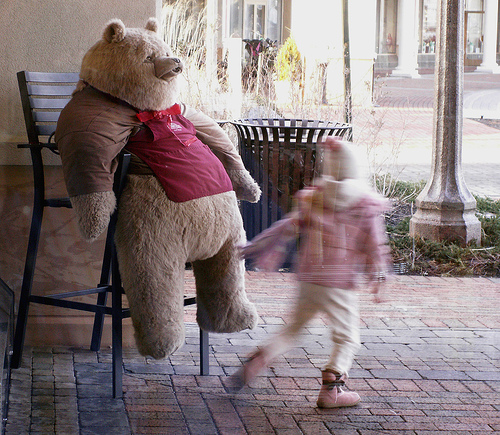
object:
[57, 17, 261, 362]
teddy bear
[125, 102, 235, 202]
apron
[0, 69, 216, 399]
chair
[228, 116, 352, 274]
garbage can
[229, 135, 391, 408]
girl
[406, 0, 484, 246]
lamp post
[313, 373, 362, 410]
boot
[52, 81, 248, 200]
t shirt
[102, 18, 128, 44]
ear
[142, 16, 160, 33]
ear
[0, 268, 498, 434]
sidewalk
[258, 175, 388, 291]
coat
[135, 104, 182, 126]
bowtie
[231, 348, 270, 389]
boot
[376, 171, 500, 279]
grass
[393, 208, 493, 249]
base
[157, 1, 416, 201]
grasses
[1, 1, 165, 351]
wall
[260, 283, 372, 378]
pants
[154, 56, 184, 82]
snout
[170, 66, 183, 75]
mouth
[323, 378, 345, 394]
bow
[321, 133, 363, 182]
hat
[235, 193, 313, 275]
scarf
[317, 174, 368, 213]
hood